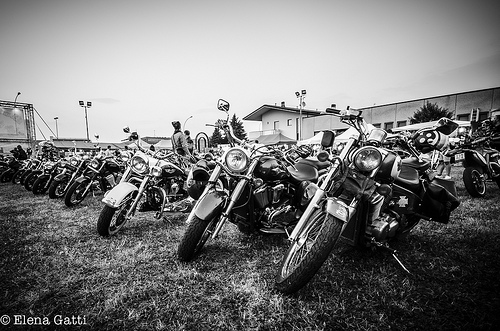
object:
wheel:
[272, 204, 344, 292]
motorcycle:
[280, 107, 456, 291]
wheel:
[178, 193, 224, 260]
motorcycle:
[178, 99, 313, 261]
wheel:
[97, 183, 138, 237]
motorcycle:
[96, 127, 187, 237]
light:
[353, 147, 382, 171]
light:
[226, 149, 248, 170]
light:
[131, 156, 148, 172]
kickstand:
[391, 254, 411, 274]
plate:
[455, 153, 465, 159]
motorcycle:
[446, 147, 499, 198]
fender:
[327, 198, 348, 222]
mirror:
[218, 99, 229, 111]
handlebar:
[218, 99, 298, 171]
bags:
[424, 183, 459, 223]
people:
[171, 121, 193, 154]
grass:
[0, 189, 496, 328]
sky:
[2, 1, 499, 144]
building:
[247, 87, 497, 136]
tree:
[211, 113, 244, 143]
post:
[295, 90, 307, 141]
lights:
[302, 90, 306, 94]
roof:
[242, 104, 320, 119]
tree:
[412, 103, 453, 122]